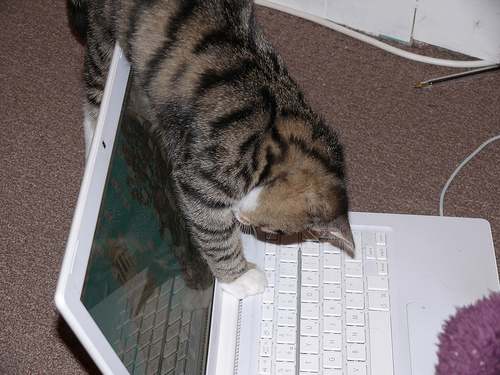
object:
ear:
[320, 213, 355, 251]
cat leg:
[171, 150, 267, 280]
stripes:
[132, 0, 263, 127]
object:
[434, 290, 499, 374]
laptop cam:
[102, 140, 107, 149]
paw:
[213, 260, 269, 300]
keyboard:
[256, 229, 393, 375]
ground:
[406, 139, 411, 142]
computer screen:
[79, 66, 217, 375]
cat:
[66, 1, 357, 301]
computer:
[53, 39, 500, 375]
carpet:
[355, 100, 430, 190]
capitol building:
[106, 237, 200, 374]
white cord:
[438, 135, 499, 216]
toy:
[425, 284, 500, 375]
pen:
[420, 67, 500, 87]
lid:
[51, 41, 230, 375]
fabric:
[437, 291, 499, 374]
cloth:
[435, 290, 500, 375]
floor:
[0, 0, 500, 375]